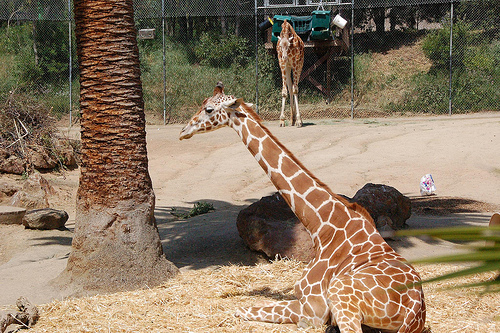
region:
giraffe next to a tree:
[68, 81, 421, 322]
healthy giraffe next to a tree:
[70, 69, 427, 324]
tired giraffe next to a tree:
[91, 73, 425, 318]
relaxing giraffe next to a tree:
[64, 77, 418, 326]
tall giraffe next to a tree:
[70, 82, 421, 327]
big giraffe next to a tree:
[67, 66, 437, 329]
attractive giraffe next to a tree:
[62, 87, 433, 321]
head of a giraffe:
[170, 84, 250, 147]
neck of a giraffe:
[240, 119, 330, 224]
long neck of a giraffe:
[225, 119, 332, 219]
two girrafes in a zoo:
[177, 30, 437, 328]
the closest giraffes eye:
[201, 107, 218, 119]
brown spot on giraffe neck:
[279, 155, 299, 180]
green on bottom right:
[373, 217, 499, 324]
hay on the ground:
[103, 285, 207, 327]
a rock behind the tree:
[24, 202, 85, 230]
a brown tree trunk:
[54, 102, 161, 187]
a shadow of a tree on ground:
[136, 193, 484, 266]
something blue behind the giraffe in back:
[244, 0, 360, 58]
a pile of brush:
[0, 112, 85, 189]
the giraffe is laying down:
[166, 87, 433, 321]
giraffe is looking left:
[160, 73, 326, 200]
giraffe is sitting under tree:
[181, 66, 420, 319]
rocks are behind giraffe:
[223, 176, 460, 283]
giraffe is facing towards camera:
[255, 14, 341, 150]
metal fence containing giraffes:
[1, 1, 482, 159]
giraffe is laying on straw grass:
[11, 47, 493, 328]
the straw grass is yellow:
[21, 252, 491, 328]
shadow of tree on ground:
[119, 157, 488, 289]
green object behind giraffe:
[258, 8, 348, 63]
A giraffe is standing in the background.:
[257, 15, 320, 130]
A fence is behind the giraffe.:
[153, 4, 265, 89]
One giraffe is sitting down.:
[166, 77, 446, 331]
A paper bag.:
[410, 164, 440, 205]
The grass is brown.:
[111, 301, 207, 331]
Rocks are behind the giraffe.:
[218, 170, 417, 272]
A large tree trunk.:
[46, 2, 176, 302]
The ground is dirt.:
[343, 131, 483, 161]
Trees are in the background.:
[163, 7, 253, 66]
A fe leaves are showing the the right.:
[358, 208, 498, 321]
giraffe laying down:
[164, 72, 441, 330]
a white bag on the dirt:
[403, 157, 446, 202]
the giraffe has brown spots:
[231, 132, 408, 284]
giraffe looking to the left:
[151, 51, 260, 159]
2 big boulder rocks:
[205, 170, 420, 265]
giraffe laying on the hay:
[133, 259, 322, 331]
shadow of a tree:
[124, 160, 258, 271]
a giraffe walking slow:
[253, 2, 323, 118]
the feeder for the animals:
[262, 7, 332, 43]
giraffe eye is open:
[162, 95, 228, 133]